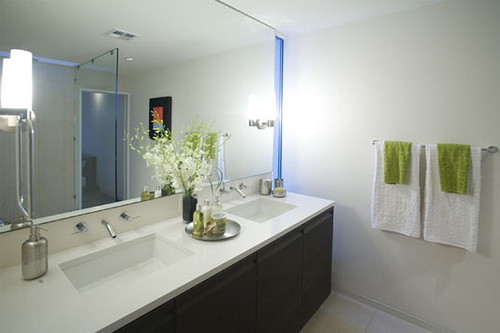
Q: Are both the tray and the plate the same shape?
A: Yes, both the tray and the plate are round.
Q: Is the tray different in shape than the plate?
A: No, both the tray and the plate are round.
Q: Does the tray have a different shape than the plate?
A: No, both the tray and the plate are round.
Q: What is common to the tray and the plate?
A: The shape, both the tray and the plate are round.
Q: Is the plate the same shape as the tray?
A: Yes, both the plate and the tray are round.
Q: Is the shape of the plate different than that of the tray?
A: No, both the plate and the tray are round.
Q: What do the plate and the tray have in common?
A: The shape, both the plate and the tray are round.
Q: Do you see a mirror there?
A: Yes, there is a mirror.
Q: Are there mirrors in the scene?
A: Yes, there is a mirror.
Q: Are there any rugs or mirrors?
A: Yes, there is a mirror.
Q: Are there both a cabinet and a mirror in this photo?
A: Yes, there are both a mirror and a cabinet.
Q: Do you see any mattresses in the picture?
A: No, there are no mattresses.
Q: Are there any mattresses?
A: No, there are no mattresses.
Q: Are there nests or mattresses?
A: No, there are no mattresses or nests.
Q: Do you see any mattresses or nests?
A: No, there are no mattresses or nests.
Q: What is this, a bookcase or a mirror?
A: This is a mirror.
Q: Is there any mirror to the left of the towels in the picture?
A: Yes, there is a mirror to the left of the towels.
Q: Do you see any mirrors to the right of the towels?
A: No, the mirror is to the left of the towels.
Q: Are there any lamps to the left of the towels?
A: No, there is a mirror to the left of the towels.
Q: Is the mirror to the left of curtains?
A: No, the mirror is to the left of the towels.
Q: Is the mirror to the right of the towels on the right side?
A: No, the mirror is to the left of the towels.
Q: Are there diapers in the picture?
A: No, there are no diapers.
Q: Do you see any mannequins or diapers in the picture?
A: No, there are no diapers or mannequins.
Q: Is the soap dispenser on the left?
A: Yes, the soap dispenser is on the left of the image.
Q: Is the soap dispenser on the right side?
A: No, the soap dispenser is on the left of the image.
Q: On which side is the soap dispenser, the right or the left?
A: The soap dispenser is on the left of the image.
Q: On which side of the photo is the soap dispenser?
A: The soap dispenser is on the left of the image.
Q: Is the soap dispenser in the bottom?
A: Yes, the soap dispenser is in the bottom of the image.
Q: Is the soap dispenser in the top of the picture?
A: No, the soap dispenser is in the bottom of the image.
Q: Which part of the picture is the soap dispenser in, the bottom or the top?
A: The soap dispenser is in the bottom of the image.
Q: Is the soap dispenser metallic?
A: Yes, the soap dispenser is metallic.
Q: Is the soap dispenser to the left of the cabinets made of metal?
A: Yes, the soap dispenser is made of metal.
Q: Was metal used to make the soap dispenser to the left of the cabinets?
A: Yes, the soap dispenser is made of metal.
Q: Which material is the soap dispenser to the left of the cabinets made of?
A: The soap dispenser is made of metal.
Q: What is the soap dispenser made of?
A: The soap dispenser is made of metal.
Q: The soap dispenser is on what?
A: The soap dispenser is on the counter top.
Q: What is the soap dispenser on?
A: The soap dispenser is on the counter top.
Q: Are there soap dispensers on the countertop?
A: Yes, there is a soap dispenser on the countertop.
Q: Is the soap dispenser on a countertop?
A: Yes, the soap dispenser is on a countertop.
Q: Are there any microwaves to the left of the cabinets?
A: No, there is a soap dispenser to the left of the cabinets.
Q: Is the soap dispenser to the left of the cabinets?
A: Yes, the soap dispenser is to the left of the cabinets.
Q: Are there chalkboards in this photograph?
A: No, there are no chalkboards.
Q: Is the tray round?
A: Yes, the tray is round.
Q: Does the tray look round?
A: Yes, the tray is round.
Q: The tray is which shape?
A: The tray is round.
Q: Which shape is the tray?
A: The tray is round.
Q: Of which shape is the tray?
A: The tray is round.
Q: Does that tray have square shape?
A: No, the tray is round.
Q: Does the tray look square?
A: No, the tray is round.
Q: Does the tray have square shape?
A: No, the tray is round.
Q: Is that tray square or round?
A: The tray is round.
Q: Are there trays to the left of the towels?
A: Yes, there is a tray to the left of the towels.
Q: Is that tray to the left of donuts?
A: No, the tray is to the left of the towels.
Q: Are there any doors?
A: Yes, there is a door.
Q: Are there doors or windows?
A: Yes, there is a door.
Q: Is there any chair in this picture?
A: No, there are no chairs.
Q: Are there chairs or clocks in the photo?
A: No, there are no chairs or clocks.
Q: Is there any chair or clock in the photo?
A: No, there are no chairs or clocks.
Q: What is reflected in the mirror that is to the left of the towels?
A: The door is reflected in the mirror.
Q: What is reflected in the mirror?
A: The door is reflected in the mirror.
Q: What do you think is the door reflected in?
A: The door is reflected in the mirror.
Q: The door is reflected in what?
A: The door is reflected in the mirror.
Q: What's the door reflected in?
A: The door is reflected in the mirror.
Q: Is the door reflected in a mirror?
A: Yes, the door is reflected in a mirror.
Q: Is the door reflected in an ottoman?
A: No, the door is reflected in a mirror.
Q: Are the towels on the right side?
A: Yes, the towels are on the right of the image.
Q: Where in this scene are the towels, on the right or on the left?
A: The towels are on the right of the image.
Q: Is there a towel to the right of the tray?
A: Yes, there are towels to the right of the tray.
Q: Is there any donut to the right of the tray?
A: No, there are towels to the right of the tray.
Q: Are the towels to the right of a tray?
A: Yes, the towels are to the right of a tray.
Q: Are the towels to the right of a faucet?
A: No, the towels are to the right of a tray.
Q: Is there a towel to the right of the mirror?
A: Yes, there are towels to the right of the mirror.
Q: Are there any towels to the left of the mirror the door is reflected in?
A: No, the towels are to the right of the mirror.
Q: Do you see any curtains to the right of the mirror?
A: No, there are towels to the right of the mirror.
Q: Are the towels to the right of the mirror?
A: Yes, the towels are to the right of the mirror.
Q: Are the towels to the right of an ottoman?
A: No, the towels are to the right of the mirror.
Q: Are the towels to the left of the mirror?
A: No, the towels are to the right of the mirror.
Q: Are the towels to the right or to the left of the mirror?
A: The towels are to the right of the mirror.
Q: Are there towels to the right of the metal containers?
A: Yes, there are towels to the right of the containers.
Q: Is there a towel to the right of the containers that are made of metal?
A: Yes, there are towels to the right of the containers.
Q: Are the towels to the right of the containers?
A: Yes, the towels are to the right of the containers.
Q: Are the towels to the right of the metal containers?
A: Yes, the towels are to the right of the containers.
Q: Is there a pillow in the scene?
A: No, there are no pillows.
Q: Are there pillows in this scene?
A: No, there are no pillows.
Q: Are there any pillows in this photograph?
A: No, there are no pillows.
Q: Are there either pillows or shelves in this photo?
A: No, there are no pillows or shelves.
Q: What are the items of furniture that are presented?
A: The pieces of furniture are cabinets.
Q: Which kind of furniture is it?
A: The pieces of furniture are cabinets.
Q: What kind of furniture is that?
A: These are cabinets.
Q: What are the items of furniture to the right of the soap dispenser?
A: The pieces of furniture are cabinets.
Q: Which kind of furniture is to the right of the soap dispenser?
A: The pieces of furniture are cabinets.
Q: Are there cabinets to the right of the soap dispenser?
A: Yes, there are cabinets to the right of the soap dispenser.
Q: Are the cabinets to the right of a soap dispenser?
A: Yes, the cabinets are to the right of a soap dispenser.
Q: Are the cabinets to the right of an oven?
A: No, the cabinets are to the right of a soap dispenser.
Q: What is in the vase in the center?
A: The flowers are in the vase.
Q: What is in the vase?
A: The flowers are in the vase.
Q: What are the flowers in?
A: The flowers are in the vase.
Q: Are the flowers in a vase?
A: Yes, the flowers are in a vase.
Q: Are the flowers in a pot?
A: No, the flowers are in a vase.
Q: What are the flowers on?
A: The flowers are on the countertop.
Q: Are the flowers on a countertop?
A: Yes, the flowers are on a countertop.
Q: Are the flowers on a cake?
A: No, the flowers are on a countertop.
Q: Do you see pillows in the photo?
A: No, there are no pillows.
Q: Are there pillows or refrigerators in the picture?
A: No, there are no pillows or refrigerators.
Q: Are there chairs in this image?
A: No, there are no chairs.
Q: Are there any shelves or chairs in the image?
A: No, there are no chairs or shelves.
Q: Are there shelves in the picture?
A: No, there are no shelves.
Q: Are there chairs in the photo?
A: No, there are no chairs.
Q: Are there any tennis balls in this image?
A: No, there are no tennis balls.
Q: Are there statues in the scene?
A: No, there are no statues.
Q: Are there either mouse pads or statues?
A: No, there are no statues or mouse pads.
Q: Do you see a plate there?
A: Yes, there is a plate.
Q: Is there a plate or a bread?
A: Yes, there is a plate.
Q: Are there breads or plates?
A: Yes, there is a plate.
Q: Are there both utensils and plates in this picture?
A: No, there is a plate but no utensils.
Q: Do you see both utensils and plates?
A: No, there is a plate but no utensils.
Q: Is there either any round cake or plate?
A: Yes, there is a round plate.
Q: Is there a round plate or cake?
A: Yes, there is a round plate.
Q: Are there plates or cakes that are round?
A: Yes, the plate is round.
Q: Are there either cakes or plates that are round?
A: Yes, the plate is round.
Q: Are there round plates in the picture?
A: Yes, there is a round plate.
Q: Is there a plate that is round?
A: Yes, there is a plate that is round.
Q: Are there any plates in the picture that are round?
A: Yes, there is a plate that is round.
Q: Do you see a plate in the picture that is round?
A: Yes, there is a plate that is round.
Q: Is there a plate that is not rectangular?
A: Yes, there is a round plate.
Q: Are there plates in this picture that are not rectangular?
A: Yes, there is a round plate.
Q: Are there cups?
A: No, there are no cups.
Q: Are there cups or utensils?
A: No, there are no cups or utensils.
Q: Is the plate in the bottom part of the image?
A: Yes, the plate is in the bottom of the image.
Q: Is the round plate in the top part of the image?
A: No, the plate is in the bottom of the image.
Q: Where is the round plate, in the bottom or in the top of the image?
A: The plate is in the bottom of the image.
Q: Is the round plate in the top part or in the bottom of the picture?
A: The plate is in the bottom of the image.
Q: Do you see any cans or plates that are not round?
A: No, there is a plate but it is round.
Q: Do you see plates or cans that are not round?
A: No, there is a plate but it is round.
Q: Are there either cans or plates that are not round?
A: No, there is a plate but it is round.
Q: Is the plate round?
A: Yes, the plate is round.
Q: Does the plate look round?
A: Yes, the plate is round.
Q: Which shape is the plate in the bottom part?
A: The plate is round.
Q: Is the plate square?
A: No, the plate is round.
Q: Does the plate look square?
A: No, the plate is round.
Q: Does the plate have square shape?
A: No, the plate is round.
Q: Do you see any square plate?
A: No, there is a plate but it is round.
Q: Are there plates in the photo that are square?
A: No, there is a plate but it is round.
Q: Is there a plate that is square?
A: No, there is a plate but it is round.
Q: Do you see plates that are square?
A: No, there is a plate but it is round.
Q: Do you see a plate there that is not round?
A: No, there is a plate but it is round.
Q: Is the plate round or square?
A: The plate is round.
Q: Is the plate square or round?
A: The plate is round.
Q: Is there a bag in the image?
A: No, there are no bags.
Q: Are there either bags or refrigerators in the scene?
A: No, there are no bags or refrigerators.